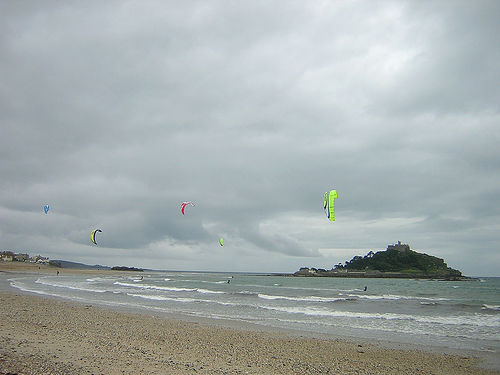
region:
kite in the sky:
[315, 180, 350, 235]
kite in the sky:
[210, 222, 231, 247]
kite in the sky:
[165, 190, 195, 222]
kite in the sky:
[75, 221, 110, 246]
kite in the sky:
[31, 190, 61, 230]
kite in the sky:
[105, 67, 127, 104]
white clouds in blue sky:
[68, 55, 133, 100]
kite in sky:
[310, 169, 347, 231]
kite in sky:
[175, 192, 210, 226]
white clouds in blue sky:
[195, 99, 250, 134]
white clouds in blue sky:
[384, 58, 431, 119]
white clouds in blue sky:
[115, 182, 133, 197]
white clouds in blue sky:
[25, 3, 96, 41]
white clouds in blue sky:
[241, 61, 272, 88]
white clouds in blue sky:
[195, 62, 247, 129]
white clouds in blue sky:
[257, 38, 305, 90]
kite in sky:
[317, 183, 342, 218]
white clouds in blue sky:
[168, 19, 226, 47]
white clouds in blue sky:
[378, 81, 479, 152]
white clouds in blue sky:
[58, 186, 88, 203]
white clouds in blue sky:
[222, 52, 293, 103]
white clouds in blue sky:
[231, 211, 271, 241]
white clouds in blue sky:
[422, 153, 446, 190]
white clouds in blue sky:
[61, 118, 101, 150]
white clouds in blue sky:
[25, 21, 80, 58]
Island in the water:
[276, 240, 483, 282]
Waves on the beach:
[2, 263, 498, 340]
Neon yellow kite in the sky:
[318, 184, 339, 224]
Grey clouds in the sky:
[1, 0, 499, 280]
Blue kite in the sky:
[41, 203, 50, 215]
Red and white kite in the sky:
[176, 199, 196, 216]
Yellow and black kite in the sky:
[87, 225, 104, 247]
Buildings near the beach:
[0, 249, 57, 269]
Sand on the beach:
[0, 293, 497, 372]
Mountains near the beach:
[48, 257, 116, 272]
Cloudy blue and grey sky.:
[2, 2, 497, 276]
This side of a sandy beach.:
[3, 297, 477, 372]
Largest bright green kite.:
[322, 189, 338, 221]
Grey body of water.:
[23, 268, 498, 350]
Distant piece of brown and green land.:
[297, 239, 462, 279]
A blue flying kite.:
[41, 204, 50, 214]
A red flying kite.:
[177, 202, 196, 215]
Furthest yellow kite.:
[217, 237, 225, 247]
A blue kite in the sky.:
[42, 204, 49, 214]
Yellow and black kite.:
[88, 226, 103, 246]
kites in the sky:
[8, 128, 482, 345]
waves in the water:
[32, 245, 477, 352]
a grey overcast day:
[12, 5, 499, 315]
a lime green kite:
[303, 170, 368, 238]